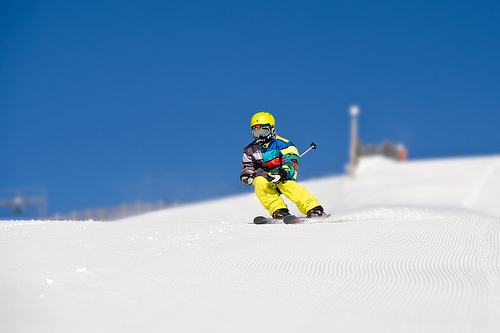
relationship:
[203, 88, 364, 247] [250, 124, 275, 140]
skier wearing goggles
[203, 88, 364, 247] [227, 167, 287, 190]
skier with gloves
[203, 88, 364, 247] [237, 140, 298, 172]
skier wearing jacket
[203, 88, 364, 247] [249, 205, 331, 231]
skier with skiboards